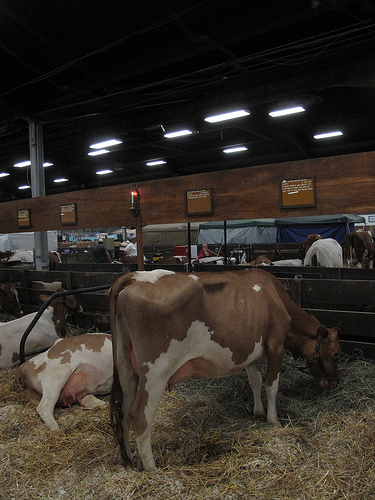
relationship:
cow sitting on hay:
[89, 253, 327, 474] [251, 401, 374, 498]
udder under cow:
[55, 381, 88, 411] [106, 267, 341, 479]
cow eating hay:
[106, 267, 341, 479] [330, 402, 373, 498]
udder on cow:
[55, 381, 88, 411] [112, 264, 344, 476]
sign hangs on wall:
[277, 174, 316, 210] [1, 144, 372, 232]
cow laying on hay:
[15, 327, 116, 421] [0, 350, 371, 497]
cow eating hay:
[106, 267, 341, 479] [1, 323, 372, 499]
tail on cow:
[100, 267, 139, 472] [95, 251, 347, 478]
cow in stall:
[106, 267, 341, 479] [0, 270, 373, 498]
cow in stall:
[15, 327, 117, 432] [0, 270, 373, 498]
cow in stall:
[0, 289, 84, 367] [0, 270, 373, 498]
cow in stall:
[1, 282, 24, 316] [0, 270, 373, 498]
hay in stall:
[1, 323, 372, 499] [4, 6, 366, 495]